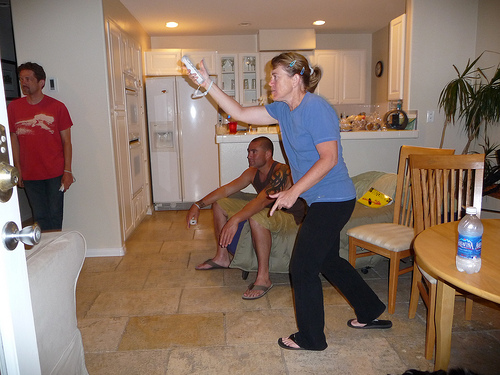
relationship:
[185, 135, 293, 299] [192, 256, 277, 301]
guy wearing flip flops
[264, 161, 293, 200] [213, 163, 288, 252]
tatoo on arm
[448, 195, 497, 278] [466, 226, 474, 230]
bottle has water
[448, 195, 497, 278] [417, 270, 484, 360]
bottle on table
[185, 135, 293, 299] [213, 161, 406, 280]
guy sitting in armchair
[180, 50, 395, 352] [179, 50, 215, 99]
people holding controller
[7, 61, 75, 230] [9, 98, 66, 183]
guy wearing red shirt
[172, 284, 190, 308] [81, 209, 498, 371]
lines on floor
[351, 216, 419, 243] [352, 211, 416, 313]
seat on chair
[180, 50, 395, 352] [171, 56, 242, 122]
people has woman's hand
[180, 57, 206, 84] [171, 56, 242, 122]
control in woman's hand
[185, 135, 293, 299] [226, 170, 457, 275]
guy sitting on couch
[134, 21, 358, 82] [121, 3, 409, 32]
lights in ceiling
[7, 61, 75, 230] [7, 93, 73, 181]
guy wearing red shirt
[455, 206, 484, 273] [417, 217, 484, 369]
bottle placed on table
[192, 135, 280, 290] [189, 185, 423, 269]
guy sitting on couch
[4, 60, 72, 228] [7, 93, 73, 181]
guy standing in red shirt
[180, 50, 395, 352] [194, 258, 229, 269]
people has shoes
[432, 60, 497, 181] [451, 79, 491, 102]
plants has green leaves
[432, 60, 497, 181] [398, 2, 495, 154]
plants near wall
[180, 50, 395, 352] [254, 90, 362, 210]
people has shirt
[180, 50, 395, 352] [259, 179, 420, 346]
people wears pants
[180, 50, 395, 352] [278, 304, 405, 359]
people wears shoes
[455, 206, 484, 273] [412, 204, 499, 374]
bottle on table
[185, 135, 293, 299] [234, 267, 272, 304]
guy wears shoes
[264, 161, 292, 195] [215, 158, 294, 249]
tatoo on arm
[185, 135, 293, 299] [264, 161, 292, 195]
guy has tatoo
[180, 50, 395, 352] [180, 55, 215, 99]
people playing game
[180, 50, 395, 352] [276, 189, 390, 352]
people wearing pants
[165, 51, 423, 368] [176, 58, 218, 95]
people playing game